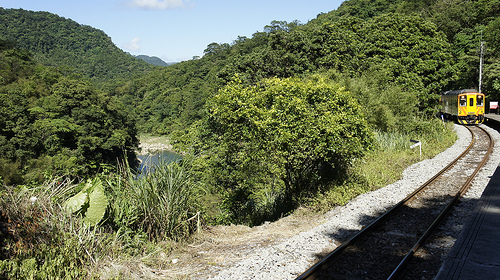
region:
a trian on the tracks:
[444, 83, 497, 150]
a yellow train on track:
[446, 92, 497, 150]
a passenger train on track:
[427, 77, 496, 145]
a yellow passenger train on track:
[439, 76, 498, 163]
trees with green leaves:
[194, 33, 357, 250]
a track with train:
[427, 65, 499, 197]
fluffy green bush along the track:
[122, 158, 222, 238]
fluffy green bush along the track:
[15, 92, 142, 191]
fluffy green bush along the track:
[185, 86, 306, 222]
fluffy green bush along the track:
[282, 70, 378, 184]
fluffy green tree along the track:
[345, 5, 455, 103]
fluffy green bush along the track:
[235, 27, 331, 88]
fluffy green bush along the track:
[445, 13, 499, 93]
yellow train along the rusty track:
[441, 86, 489, 126]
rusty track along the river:
[300, 120, 492, 279]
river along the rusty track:
[130, 136, 187, 186]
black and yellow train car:
[438, 87, 481, 120]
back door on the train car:
[464, 97, 475, 113]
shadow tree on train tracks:
[320, 183, 497, 275]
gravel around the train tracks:
[283, 107, 495, 279]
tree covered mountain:
[5, 6, 163, 78]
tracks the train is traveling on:
[313, 112, 499, 275]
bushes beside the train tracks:
[13, 57, 420, 274]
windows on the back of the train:
[460, 95, 480, 104]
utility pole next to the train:
[474, 39, 486, 97]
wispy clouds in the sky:
[123, 6, 188, 54]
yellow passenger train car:
[445, 89, 485, 126]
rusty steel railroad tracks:
[294, 190, 466, 279]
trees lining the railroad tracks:
[0, 1, 436, 171]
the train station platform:
[484, 105, 499, 279]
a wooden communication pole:
[474, 39, 491, 91]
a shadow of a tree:
[298, 194, 499, 279]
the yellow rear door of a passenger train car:
[467, 92, 477, 117]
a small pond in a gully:
[137, 147, 184, 174]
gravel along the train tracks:
[298, 124, 498, 279]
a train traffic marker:
[407, 137, 423, 161]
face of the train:
[439, 85, 494, 136]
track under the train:
[455, 123, 495, 157]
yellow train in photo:
[426, 80, 493, 133]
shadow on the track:
[358, 171, 468, 243]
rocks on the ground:
[443, 126, 483, 155]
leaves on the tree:
[355, 19, 453, 94]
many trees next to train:
[9, 13, 423, 212]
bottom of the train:
[448, 110, 489, 133]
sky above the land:
[135, 9, 219, 56]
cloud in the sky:
[125, 1, 180, 17]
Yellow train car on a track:
[442, 86, 483, 123]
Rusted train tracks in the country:
[286, 123, 491, 276]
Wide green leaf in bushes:
[59, 175, 106, 227]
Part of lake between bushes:
[135, 148, 182, 170]